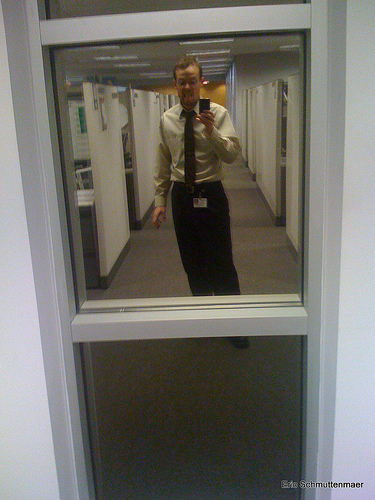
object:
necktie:
[179, 109, 197, 185]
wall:
[82, 76, 175, 288]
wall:
[233, 54, 301, 262]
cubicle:
[116, 83, 140, 237]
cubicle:
[158, 90, 173, 116]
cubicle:
[276, 73, 304, 265]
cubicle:
[247, 88, 257, 184]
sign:
[203, 80, 210, 84]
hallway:
[85, 163, 303, 500]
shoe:
[227, 336, 251, 348]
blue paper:
[78, 106, 87, 133]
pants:
[170, 180, 240, 297]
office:
[52, 53, 304, 500]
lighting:
[178, 38, 234, 76]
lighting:
[94, 55, 171, 78]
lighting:
[280, 45, 301, 49]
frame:
[16, 0, 346, 500]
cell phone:
[198, 98, 210, 113]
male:
[153, 57, 251, 348]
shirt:
[153, 94, 242, 207]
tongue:
[186, 94, 192, 100]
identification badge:
[193, 198, 208, 209]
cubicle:
[68, 97, 100, 288]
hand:
[196, 110, 216, 131]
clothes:
[153, 96, 242, 296]